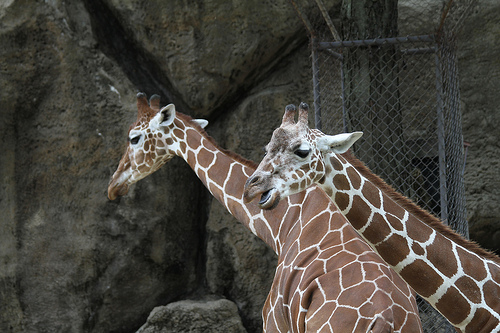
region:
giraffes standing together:
[104, 72, 499, 329]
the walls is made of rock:
[2, 2, 498, 247]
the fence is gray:
[286, 1, 498, 261]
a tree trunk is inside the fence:
[306, 7, 499, 312]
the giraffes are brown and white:
[88, 75, 499, 328]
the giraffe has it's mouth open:
[230, 96, 377, 229]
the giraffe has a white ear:
[241, 94, 369, 218]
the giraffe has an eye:
[237, 96, 359, 211]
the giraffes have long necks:
[96, 73, 491, 312]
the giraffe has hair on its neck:
[233, 95, 499, 305]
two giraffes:
[58, 58, 453, 323]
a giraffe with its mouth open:
[234, 100, 353, 216]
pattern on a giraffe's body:
[271, 222, 338, 331]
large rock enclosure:
[1, 20, 392, 293]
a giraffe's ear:
[308, 122, 370, 154]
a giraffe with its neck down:
[84, 96, 310, 219]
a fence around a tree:
[279, 28, 454, 160]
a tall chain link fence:
[247, 27, 460, 162]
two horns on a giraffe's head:
[269, 95, 319, 139]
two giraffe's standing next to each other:
[57, 57, 447, 320]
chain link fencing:
[301, 13, 466, 153]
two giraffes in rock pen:
[103, 70, 462, 328]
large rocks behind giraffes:
[36, 6, 258, 106]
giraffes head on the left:
[115, 77, 246, 223]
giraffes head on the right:
[242, 106, 377, 233]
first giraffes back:
[235, 167, 403, 330]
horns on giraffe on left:
[127, 91, 166, 117]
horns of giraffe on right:
[285, 77, 323, 126]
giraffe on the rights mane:
[351, 147, 498, 266]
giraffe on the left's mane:
[165, 94, 270, 170]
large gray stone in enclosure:
[147, 295, 249, 332]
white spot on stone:
[97, 70, 124, 110]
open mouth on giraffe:
[238, 171, 290, 209]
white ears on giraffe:
[316, 122, 370, 159]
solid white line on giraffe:
[398, 240, 462, 279]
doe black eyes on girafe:
[116, 130, 160, 152]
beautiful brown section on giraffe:
[416, 222, 428, 240]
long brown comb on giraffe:
[346, 157, 483, 242]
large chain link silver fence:
[284, 3, 466, 123]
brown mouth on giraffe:
[96, 167, 163, 219]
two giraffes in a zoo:
[95, 65, 490, 329]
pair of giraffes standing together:
[85, 71, 422, 316]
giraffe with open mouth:
[238, 97, 368, 210]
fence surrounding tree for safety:
[284, 13, 467, 154]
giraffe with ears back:
[91, 95, 256, 220]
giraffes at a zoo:
[24, 34, 451, 294]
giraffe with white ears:
[256, 86, 361, 203]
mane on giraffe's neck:
[302, 125, 477, 265]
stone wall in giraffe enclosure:
[15, 34, 172, 227]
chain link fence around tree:
[272, 43, 459, 145]